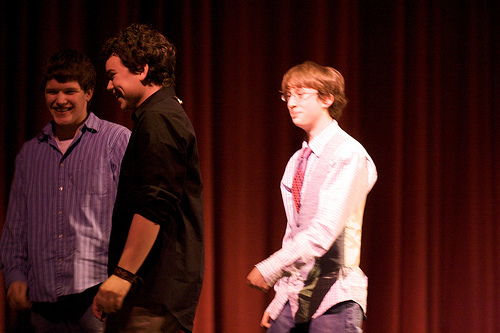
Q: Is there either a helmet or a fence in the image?
A: No, there are no fences or helmets.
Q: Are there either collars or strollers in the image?
A: Yes, there is a collar.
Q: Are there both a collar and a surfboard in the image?
A: No, there is a collar but no surfboards.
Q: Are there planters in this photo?
A: No, there are no planters.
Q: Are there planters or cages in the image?
A: No, there are no planters or cages.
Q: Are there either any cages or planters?
A: No, there are no planters or cages.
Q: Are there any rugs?
A: No, there are no rugs.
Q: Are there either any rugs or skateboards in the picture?
A: No, there are no rugs or skateboards.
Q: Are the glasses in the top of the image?
A: Yes, the glasses are in the top of the image.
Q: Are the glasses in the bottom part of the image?
A: No, the glasses are in the top of the image.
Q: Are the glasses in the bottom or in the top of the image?
A: The glasses are in the top of the image.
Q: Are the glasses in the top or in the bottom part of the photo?
A: The glasses are in the top of the image.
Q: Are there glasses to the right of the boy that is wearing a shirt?
A: Yes, there are glasses to the right of the boy.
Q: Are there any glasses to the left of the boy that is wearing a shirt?
A: No, the glasses are to the right of the boy.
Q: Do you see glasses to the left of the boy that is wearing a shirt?
A: No, the glasses are to the right of the boy.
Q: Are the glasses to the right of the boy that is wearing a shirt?
A: Yes, the glasses are to the right of the boy.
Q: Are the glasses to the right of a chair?
A: No, the glasses are to the right of the boy.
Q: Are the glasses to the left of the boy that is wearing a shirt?
A: No, the glasses are to the right of the boy.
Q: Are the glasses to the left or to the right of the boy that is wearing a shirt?
A: The glasses are to the right of the boy.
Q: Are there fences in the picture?
A: No, there are no fences.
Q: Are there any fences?
A: No, there are no fences.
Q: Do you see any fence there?
A: No, there are no fences.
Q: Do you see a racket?
A: No, there are no rackets.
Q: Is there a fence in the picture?
A: No, there are no fences.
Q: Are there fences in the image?
A: No, there are no fences.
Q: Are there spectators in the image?
A: No, there are no spectators.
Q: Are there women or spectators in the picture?
A: No, there are no spectators or women.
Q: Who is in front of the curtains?
A: The boy is in front of the curtains.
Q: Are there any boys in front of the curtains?
A: Yes, there is a boy in front of the curtains.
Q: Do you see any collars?
A: Yes, there is a collar.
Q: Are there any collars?
A: Yes, there is a collar.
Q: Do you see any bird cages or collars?
A: Yes, there is a collar.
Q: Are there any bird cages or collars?
A: Yes, there is a collar.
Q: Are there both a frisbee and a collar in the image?
A: No, there is a collar but no frisbees.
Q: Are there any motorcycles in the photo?
A: No, there are no motorcycles.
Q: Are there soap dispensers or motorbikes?
A: No, there are no motorbikes or soap dispensers.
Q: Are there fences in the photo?
A: No, there are no fences.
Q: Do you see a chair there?
A: No, there are no chairs.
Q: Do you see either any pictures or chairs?
A: No, there are no chairs or pictures.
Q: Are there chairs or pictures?
A: No, there are no chairs or pictures.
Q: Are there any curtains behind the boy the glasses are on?
A: Yes, there are curtains behind the boy.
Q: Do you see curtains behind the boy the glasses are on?
A: Yes, there are curtains behind the boy.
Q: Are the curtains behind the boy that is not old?
A: Yes, the curtains are behind the boy.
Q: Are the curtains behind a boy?
A: Yes, the curtains are behind a boy.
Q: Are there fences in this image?
A: No, there are no fences.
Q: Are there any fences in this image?
A: No, there are no fences.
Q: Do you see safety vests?
A: No, there are no safety vests.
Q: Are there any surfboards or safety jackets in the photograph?
A: No, there are no safety jackets or surfboards.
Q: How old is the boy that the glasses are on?
A: The boy is young.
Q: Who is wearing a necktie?
A: The boy is wearing a necktie.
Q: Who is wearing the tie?
A: The boy is wearing a necktie.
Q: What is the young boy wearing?
A: The boy is wearing a necktie.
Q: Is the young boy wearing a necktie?
A: Yes, the boy is wearing a necktie.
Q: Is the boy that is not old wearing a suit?
A: No, the boy is wearing a necktie.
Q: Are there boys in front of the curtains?
A: Yes, there is a boy in front of the curtains.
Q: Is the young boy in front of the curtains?
A: Yes, the boy is in front of the curtains.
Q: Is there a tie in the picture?
A: Yes, there is a tie.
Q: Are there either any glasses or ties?
A: Yes, there is a tie.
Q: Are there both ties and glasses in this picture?
A: Yes, there are both a tie and glasses.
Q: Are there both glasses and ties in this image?
A: Yes, there are both a tie and glasses.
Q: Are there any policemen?
A: No, there are no policemen.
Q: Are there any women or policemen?
A: No, there are no policemen or women.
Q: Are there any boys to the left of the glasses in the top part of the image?
A: Yes, there is a boy to the left of the glasses.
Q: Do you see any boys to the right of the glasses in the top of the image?
A: No, the boy is to the left of the glasses.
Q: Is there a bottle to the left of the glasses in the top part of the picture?
A: No, there is a boy to the left of the glasses.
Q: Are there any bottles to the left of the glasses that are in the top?
A: No, there is a boy to the left of the glasses.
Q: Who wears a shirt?
A: The boy wears a shirt.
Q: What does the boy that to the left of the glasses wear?
A: The boy wears a shirt.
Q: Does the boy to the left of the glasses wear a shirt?
A: Yes, the boy wears a shirt.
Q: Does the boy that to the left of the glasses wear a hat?
A: No, the boy wears a shirt.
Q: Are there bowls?
A: No, there are no bowls.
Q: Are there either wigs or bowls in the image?
A: No, there are no bowls or wigs.